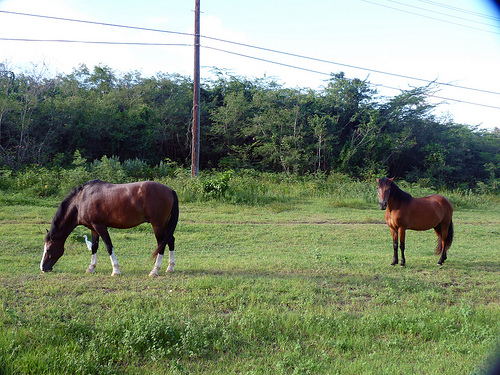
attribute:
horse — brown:
[37, 178, 182, 281]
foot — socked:
[107, 268, 126, 276]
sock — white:
[102, 251, 128, 284]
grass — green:
[13, 297, 496, 371]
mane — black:
[38, 184, 77, 237]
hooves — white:
[82, 245, 188, 287]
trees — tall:
[1, 69, 498, 187]